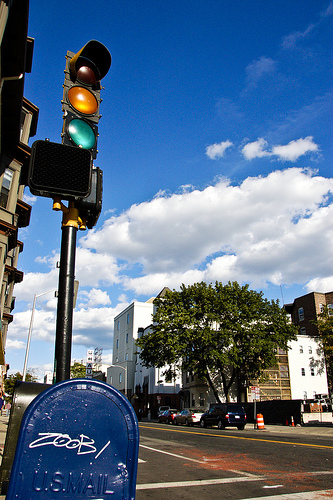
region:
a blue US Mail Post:
[15, 367, 143, 497]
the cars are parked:
[143, 396, 274, 449]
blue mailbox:
[25, 365, 145, 498]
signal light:
[73, 43, 105, 151]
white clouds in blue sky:
[126, 14, 162, 69]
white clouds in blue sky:
[121, 104, 171, 180]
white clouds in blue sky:
[116, 187, 165, 258]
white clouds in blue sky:
[99, 251, 148, 307]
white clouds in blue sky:
[17, 284, 53, 337]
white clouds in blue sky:
[158, 177, 197, 240]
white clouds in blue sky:
[215, 133, 265, 201]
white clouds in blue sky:
[229, 136, 283, 233]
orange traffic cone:
[255, 411, 266, 433]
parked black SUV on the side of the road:
[199, 403, 248, 433]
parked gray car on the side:
[171, 408, 205, 426]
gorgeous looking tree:
[143, 281, 280, 412]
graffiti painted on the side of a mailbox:
[32, 429, 120, 468]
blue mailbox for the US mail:
[8, 363, 140, 497]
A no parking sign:
[250, 384, 260, 399]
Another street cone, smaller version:
[286, 415, 298, 426]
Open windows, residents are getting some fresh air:
[300, 366, 315, 379]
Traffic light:
[30, 12, 109, 231]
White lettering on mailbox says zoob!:
[28, 426, 116, 469]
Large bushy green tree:
[136, 284, 304, 432]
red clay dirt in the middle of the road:
[163, 429, 332, 497]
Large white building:
[111, 298, 190, 396]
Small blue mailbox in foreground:
[12, 373, 139, 498]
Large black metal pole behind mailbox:
[27, 139, 106, 384]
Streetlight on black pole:
[64, 46, 106, 152]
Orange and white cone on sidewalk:
[252, 413, 267, 431]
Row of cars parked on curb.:
[150, 406, 249, 433]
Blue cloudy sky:
[5, 3, 332, 302]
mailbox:
[21, 374, 135, 488]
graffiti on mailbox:
[27, 422, 124, 461]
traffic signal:
[58, 44, 101, 154]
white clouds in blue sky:
[107, 180, 157, 233]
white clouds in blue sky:
[156, 135, 199, 230]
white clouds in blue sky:
[182, 60, 225, 163]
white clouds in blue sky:
[214, 35, 270, 136]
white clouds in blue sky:
[246, 131, 319, 187]